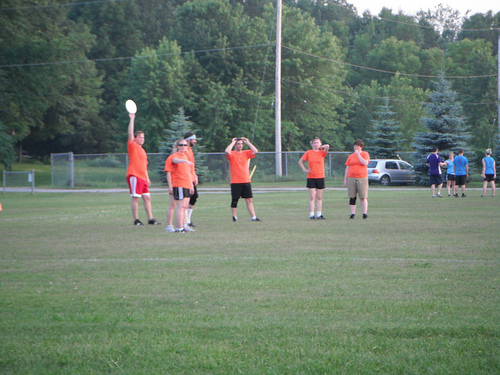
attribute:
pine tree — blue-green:
[413, 71, 473, 186]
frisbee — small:
[122, 97, 139, 115]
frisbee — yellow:
[123, 101, 137, 116]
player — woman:
[339, 139, 381, 219]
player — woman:
[296, 132, 333, 218]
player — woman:
[219, 131, 261, 226]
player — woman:
[157, 135, 201, 229]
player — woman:
[116, 93, 160, 226]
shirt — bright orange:
[123, 143, 148, 183]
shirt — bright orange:
[170, 154, 191, 187]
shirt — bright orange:
[221, 151, 256, 186]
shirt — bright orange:
[299, 145, 330, 183]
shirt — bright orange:
[346, 149, 370, 179]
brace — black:
[231, 191, 239, 209]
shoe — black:
[348, 210, 372, 220]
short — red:
[122, 99, 160, 226]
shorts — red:
[126, 167, 155, 205]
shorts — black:
[218, 173, 268, 206]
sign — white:
[26, 168, 33, 181]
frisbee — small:
[124, 92, 137, 116]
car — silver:
[325, 127, 461, 207]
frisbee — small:
[118, 74, 138, 124]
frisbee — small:
[123, 91, 145, 118]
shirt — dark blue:
[425, 153, 441, 174]